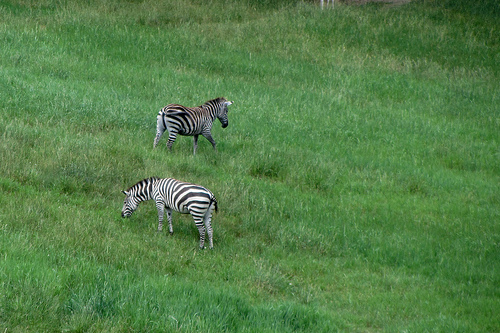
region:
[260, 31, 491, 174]
field of tall green grass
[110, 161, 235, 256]
zebra feeding on grass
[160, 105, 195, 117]
zebra's tail swishing to the side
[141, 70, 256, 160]
animal moving through the field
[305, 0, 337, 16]
thin trunks of trees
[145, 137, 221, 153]
three legs touching the ground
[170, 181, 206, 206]
striped body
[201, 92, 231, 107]
mane and ears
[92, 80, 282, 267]
two zebras in a natural habitat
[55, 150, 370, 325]
animal facing uphill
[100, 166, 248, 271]
zebra grazing in green field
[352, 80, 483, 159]
field covered in green grass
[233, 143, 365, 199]
clump of thick green grass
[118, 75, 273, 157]
zebra walking in field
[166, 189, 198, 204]
pattern on side of zebra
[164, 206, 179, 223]
black spot on leg of zebra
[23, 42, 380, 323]
two zebras in lush gassy field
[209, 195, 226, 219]
small black zebra tail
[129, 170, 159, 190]
black and white hair on back of zebra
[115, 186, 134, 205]
small black and white zebra ear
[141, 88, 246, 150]
zebra running through grass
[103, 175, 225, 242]
zebra grazing on grass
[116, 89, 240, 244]
two zebras in grass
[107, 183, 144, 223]
head of zebra grazing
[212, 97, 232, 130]
head of zebra running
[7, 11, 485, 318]
grass field zebra are in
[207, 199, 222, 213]
black tail of grazing zebra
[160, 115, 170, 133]
black tail of zebra running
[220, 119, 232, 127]
black nose of zebra running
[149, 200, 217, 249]
legs of zebra grazing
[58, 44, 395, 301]
zebras in the grass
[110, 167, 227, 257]
this zebra is eating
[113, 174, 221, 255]
this zebra is turned sideways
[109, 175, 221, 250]
the zebra is striped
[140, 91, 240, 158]
this zebra is walking away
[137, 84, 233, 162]
this zebra is striped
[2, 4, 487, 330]
the grass is long and green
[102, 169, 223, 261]
the zebra is eating grass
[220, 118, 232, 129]
his nose is black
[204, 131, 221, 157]
the zebra's leg is bent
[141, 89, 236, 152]
zebra running in field of grass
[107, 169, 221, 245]
zebra grazing on green grass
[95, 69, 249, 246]
two zebras in grass field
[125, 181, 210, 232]
stripes on grazing zebra's body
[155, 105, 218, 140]
stripes on running zebra's body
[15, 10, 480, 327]
grass field zebras are in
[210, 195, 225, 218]
black tail of grazing zebra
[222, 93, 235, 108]
ear of running zebra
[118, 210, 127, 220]
black nose of zebra grazing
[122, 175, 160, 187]
black mane of zebra